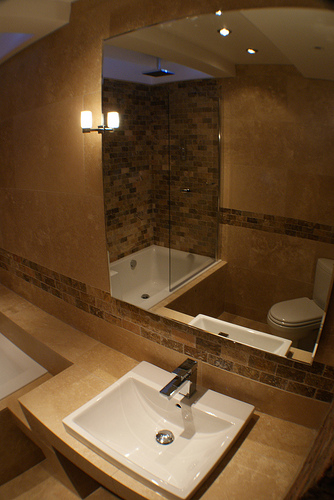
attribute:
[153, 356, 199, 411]
faucet — square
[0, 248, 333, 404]
backsplash — tiled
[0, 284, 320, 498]
counter top — brown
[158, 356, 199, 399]
faucet — silver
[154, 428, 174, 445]
drain — silver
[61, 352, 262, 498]
sink — square, white, ceramic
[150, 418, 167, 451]
drain — silver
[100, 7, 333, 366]
mirror — large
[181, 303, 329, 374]
sink — white, reflected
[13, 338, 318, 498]
counter — tan, brown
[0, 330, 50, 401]
bathtub — white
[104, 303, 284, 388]
backsplash — brown, tiled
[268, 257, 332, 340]
toilet — white, ceramic